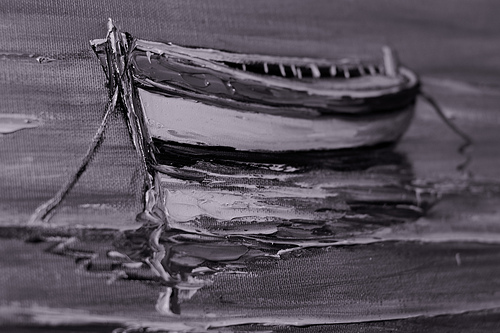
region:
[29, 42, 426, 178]
boat is in the water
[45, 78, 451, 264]
the water carries the boat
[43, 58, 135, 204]
the boat is docked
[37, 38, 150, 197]
string on the boat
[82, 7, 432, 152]
the boat is empty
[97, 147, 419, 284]
the water reflects the boat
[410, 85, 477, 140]
string at the back of the boat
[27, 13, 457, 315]
the boat isn't colored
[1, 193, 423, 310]
the waters are reflective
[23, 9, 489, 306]
a painting of a boat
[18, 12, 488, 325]
black and white painting of boat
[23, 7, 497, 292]
painting of a boat in water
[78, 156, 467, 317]
reflection of a boat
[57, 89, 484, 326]
reflection painted of a boat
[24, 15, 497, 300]
ropes attached to front and back of boat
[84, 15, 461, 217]
grey, white, and black boat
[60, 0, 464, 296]
grey, white, and black striped boat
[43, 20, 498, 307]
painting of a wooden boat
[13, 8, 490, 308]
painting of a boat on canvas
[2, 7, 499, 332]
black and white painting of a boat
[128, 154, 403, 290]
reflection of boat on the water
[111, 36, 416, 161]
hull of the boat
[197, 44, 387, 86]
cabin on the boat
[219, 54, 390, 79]
windows on the cabin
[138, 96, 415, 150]
white stripe on the hull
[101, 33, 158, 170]
post boat is tied to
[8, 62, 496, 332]
water boat is sitting in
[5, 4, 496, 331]
painting of a boat on the water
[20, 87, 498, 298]
water around the boat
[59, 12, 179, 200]
a part of the boat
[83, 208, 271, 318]
a disturbance in the water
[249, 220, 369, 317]
riddles in the water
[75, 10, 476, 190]
a boat in the water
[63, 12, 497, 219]
a ship in the water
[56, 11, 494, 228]
a steamer in the water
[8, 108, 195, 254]
a stick in the water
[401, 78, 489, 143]
a stick to hold boat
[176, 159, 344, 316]
shadow of the boat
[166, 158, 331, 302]
shadow of the ship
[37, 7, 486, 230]
picture of painted boat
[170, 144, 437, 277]
shadow of the boat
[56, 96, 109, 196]
strings of the boat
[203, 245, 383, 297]
water part of the painting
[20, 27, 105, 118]
grey colored paint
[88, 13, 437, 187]
a small boat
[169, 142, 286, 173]
boat painted into black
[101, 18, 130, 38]
tip of the wooden boat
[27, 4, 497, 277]
pastel painted boat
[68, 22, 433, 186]
wooden boat at the sea